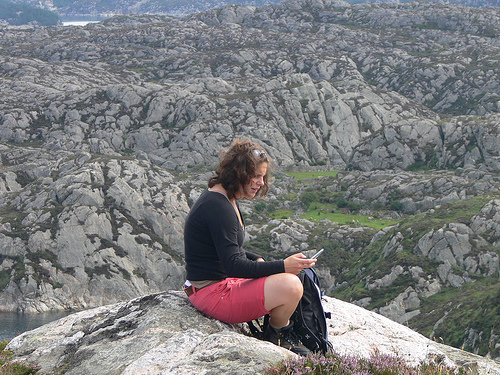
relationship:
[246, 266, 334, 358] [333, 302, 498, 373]
backpack on ground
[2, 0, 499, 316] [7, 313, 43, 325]
rocks in between lake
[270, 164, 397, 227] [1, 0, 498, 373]
green grass by mountains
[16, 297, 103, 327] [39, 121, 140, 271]
water next to hillside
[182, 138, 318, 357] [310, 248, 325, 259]
woman holding cell phone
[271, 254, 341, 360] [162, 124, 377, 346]
backpack in front of woman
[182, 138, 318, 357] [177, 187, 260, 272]
woman wearing shirt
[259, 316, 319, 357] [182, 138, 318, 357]
brown boot of woman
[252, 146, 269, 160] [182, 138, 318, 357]
glasses on a woman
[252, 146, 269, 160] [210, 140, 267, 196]
glasses on a head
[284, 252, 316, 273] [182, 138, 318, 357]
hand of woman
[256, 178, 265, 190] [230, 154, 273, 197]
nose on woman's face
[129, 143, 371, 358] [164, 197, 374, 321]
woman wearing black shirt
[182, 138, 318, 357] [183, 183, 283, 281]
woman wearing shirt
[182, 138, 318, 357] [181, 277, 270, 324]
woman wearing shorts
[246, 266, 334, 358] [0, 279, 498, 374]
backpack on ground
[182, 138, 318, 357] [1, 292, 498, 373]
woman sitting on ground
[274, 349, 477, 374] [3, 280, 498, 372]
flowers growing next to rock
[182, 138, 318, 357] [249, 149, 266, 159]
woman has glasses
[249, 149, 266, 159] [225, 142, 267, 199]
glasses are on head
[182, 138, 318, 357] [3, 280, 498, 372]
woman on rock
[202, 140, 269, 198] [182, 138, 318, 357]
hair on woman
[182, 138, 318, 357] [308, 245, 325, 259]
woman with device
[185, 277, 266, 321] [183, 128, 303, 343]
red shorts on woman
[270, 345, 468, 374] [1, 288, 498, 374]
flowers on mountain